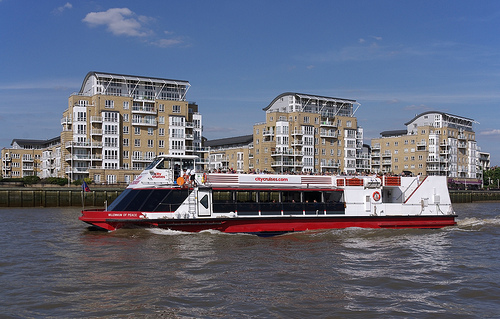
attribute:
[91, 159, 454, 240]
boat — long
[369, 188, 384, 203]
life ring — orange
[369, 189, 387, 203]
lifesaver — orange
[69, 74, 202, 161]
buildings — brown, white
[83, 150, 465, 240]
boat — white, red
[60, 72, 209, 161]
building — large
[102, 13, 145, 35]
cloud — white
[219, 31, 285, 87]
sky — clear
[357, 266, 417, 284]
waves — small